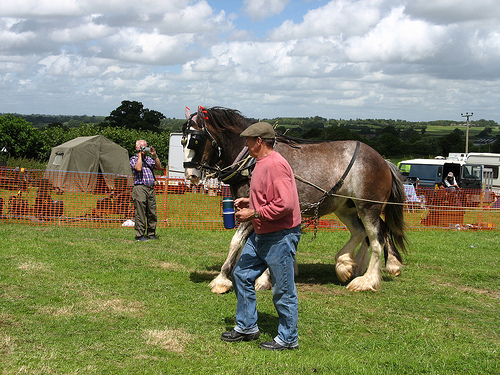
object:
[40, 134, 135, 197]
tent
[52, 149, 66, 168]
window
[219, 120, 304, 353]
man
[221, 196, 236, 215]
mug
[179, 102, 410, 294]
horse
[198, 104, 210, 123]
ribbons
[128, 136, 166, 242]
man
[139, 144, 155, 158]
video camera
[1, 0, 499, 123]
sky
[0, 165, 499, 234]
fencing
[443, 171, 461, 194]
man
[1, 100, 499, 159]
landscape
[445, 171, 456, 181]
head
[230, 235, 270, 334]
leg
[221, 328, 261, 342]
shoe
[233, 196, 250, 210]
hand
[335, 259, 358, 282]
hoof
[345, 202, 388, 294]
leg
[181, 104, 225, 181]
head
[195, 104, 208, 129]
ear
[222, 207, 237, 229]
coffee cup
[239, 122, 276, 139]
hat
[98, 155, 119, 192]
flap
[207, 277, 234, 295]
foot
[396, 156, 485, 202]
van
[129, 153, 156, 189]
checkered shirt